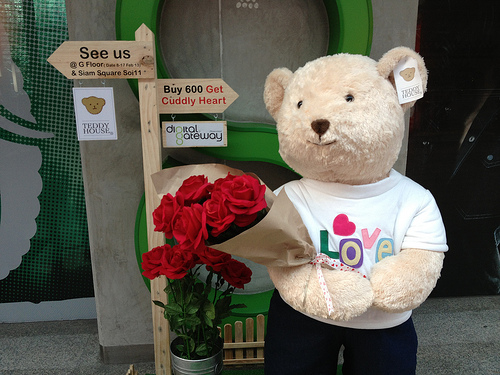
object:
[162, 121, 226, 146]
sign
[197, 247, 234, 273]
flowers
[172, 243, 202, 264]
flowers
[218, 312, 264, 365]
fence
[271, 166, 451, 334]
shirt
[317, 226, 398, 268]
love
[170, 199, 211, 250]
flower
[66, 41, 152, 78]
sign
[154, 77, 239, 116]
arrow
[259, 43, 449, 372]
bear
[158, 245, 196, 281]
flowers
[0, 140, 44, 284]
paint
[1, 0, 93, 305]
window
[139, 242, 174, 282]
roses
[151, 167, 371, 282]
bouquet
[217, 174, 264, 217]
flower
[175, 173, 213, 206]
flower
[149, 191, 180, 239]
flower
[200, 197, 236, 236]
flower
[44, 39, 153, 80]
arrows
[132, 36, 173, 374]
post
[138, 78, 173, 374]
pole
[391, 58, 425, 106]
tag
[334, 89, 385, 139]
ground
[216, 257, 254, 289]
flowers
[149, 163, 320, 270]
paper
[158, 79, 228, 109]
sign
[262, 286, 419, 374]
pants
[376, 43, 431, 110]
ear